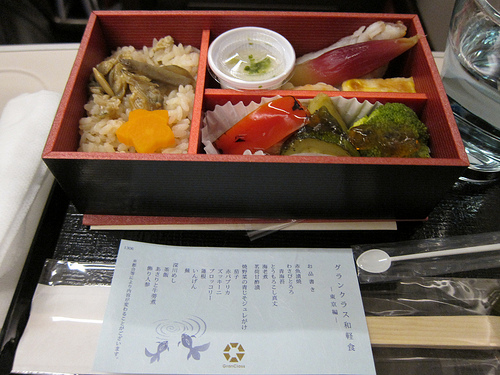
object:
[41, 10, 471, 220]
box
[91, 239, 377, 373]
paper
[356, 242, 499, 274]
utensil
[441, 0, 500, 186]
glass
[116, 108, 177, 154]
star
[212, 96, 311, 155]
tomato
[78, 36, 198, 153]
rice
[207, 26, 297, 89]
container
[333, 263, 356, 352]
writing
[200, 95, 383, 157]
paper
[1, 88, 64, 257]
napkin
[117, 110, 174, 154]
food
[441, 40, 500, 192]
water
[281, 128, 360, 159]
zucchini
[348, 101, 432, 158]
broccoli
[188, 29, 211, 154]
dividers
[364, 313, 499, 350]
wood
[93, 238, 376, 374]
receipt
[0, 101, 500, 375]
table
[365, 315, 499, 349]
utensil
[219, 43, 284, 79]
sauce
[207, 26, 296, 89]
lid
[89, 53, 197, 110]
meat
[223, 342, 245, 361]
logo